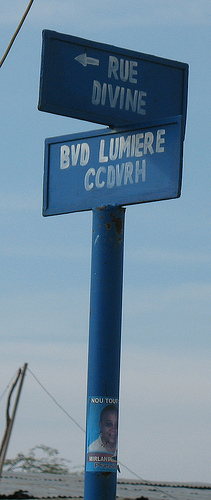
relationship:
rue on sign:
[106, 53, 145, 87] [34, 21, 191, 142]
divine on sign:
[90, 79, 146, 116] [34, 21, 191, 142]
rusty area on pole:
[95, 204, 124, 242] [80, 204, 126, 499]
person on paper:
[97, 405, 120, 455] [87, 392, 118, 470]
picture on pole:
[85, 395, 119, 471] [80, 204, 126, 499]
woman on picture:
[97, 404, 119, 451] [84, 393, 120, 473]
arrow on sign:
[75, 52, 100, 66] [26, 30, 192, 171]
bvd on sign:
[53, 143, 94, 170] [41, 112, 183, 216]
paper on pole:
[86, 393, 121, 475] [80, 204, 126, 499]